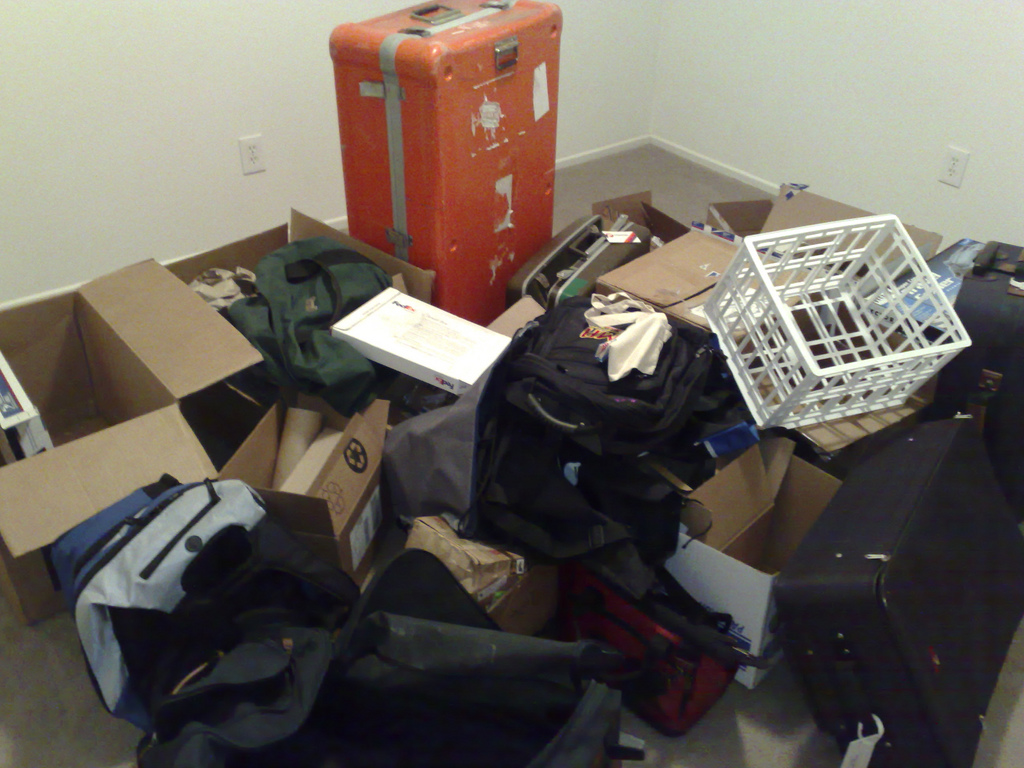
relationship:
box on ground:
[11, 207, 182, 611] [15, 235, 290, 599]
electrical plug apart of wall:
[239, 134, 264, 175] [158, 60, 299, 208]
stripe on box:
[344, 29, 472, 265] [286, 36, 587, 257]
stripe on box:
[363, 30, 429, 265] [321, 6, 563, 315]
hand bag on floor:
[567, 572, 738, 732] [722, 693, 794, 763]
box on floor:
[213, 400, 395, 592] [3, 634, 79, 756]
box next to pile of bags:
[328, 0, 566, 332] [230, 230, 712, 548]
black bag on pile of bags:
[471, 291, 716, 555] [392, 421, 745, 763]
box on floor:
[213, 400, 395, 592] [1, 608, 69, 766]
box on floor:
[0, 257, 268, 627] [1, 608, 69, 766]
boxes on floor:
[160, 209, 442, 432] [1, 608, 69, 766]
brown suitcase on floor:
[512, 207, 646, 298] [552, 131, 749, 188]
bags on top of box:
[230, 230, 416, 409] [173, 205, 444, 383]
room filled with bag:
[29, 1, 993, 764] [756, 413, 1024, 767]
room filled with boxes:
[29, 1, 993, 764] [5, 213, 444, 633]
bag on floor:
[756, 413, 1024, 767] [1, 608, 77, 760]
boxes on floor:
[5, 213, 444, 633] [1, 608, 77, 760]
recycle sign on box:
[342, 438, 369, 477] [223, 390, 392, 576]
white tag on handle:
[843, 725, 882, 764] [828, 652, 874, 726]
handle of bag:
[828, 652, 874, 726] [756, 413, 1024, 767]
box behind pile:
[328, 0, 566, 332] [57, 213, 982, 760]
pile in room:
[57, 213, 982, 760] [29, 1, 993, 764]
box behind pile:
[328, 0, 566, 332] [199, 211, 776, 763]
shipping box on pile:
[335, 280, 517, 399] [223, 243, 513, 522]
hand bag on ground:
[567, 572, 739, 732] [707, 702, 801, 763]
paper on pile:
[580, 282, 676, 382] [391, 289, 735, 763]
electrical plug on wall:
[239, 134, 264, 175] [3, 1, 237, 243]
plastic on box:
[684, 178, 972, 459] [782, 379, 942, 483]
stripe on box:
[363, 30, 429, 265] [13, 253, 271, 612]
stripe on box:
[363, 30, 429, 265] [309, 134, 586, 376]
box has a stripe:
[328, 9, 566, 278] [375, 53, 419, 255]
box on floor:
[244, 411, 396, 591] [23, 653, 90, 736]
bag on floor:
[95, 506, 340, 727] [30, 629, 76, 753]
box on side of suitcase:
[691, 450, 797, 615] [793, 485, 962, 741]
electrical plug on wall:
[239, 122, 274, 185] [73, 98, 221, 243]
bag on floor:
[170, 625, 352, 755] [17, 677, 84, 758]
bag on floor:
[756, 565, 955, 723] [715, 729, 772, 760]